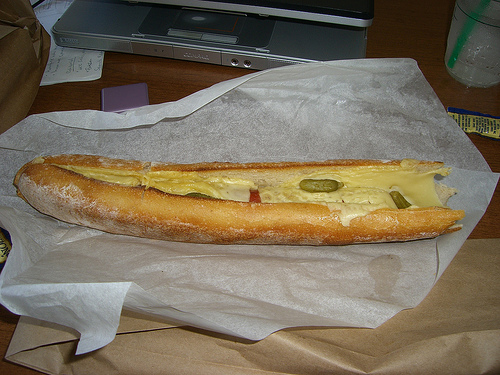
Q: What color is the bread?
A: White.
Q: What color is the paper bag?
A: Brown.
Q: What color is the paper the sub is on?
A: White.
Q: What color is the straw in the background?
A: Green.